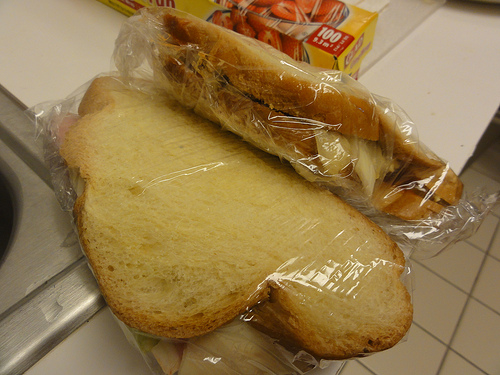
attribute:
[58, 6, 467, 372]
wrapped — sandwiches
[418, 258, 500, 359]
floor — tile, beige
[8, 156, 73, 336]
sink — steel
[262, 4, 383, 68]
box — plastic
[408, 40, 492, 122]
counter — beige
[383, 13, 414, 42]
cutting board — white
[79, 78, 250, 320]
bread — yellow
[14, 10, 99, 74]
counter top — white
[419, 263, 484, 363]
tile — tan